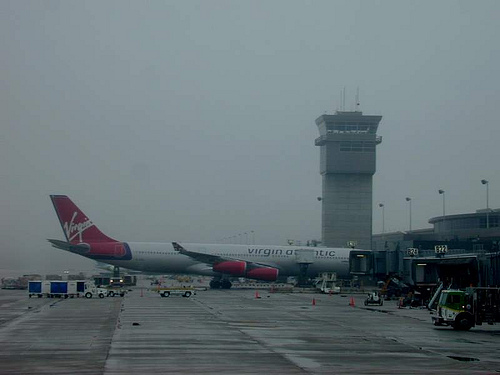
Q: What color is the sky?
A: Gray.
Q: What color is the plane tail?
A: Red.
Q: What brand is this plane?
A: Virgin.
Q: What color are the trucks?
A: White.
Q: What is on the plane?
A: Logo.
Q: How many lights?
A: 4.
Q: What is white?
A: Plane.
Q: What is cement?
A: Floor.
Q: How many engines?
A: 2.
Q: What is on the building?
A: Lights.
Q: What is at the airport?
A: Plane.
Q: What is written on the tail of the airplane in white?
A: Virgin.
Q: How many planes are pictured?
A: One.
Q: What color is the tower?
A: Grey.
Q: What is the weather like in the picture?
A: Overcast.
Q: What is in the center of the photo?
A: An airplane.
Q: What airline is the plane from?
A: Virgin Atlantic.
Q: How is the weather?
A: Rainy.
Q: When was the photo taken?
A: During the day.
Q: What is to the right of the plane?
A: The terminal.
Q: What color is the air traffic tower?
A: Gray.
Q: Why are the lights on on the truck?
A: It is dim.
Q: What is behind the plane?
A: A luggage cart.